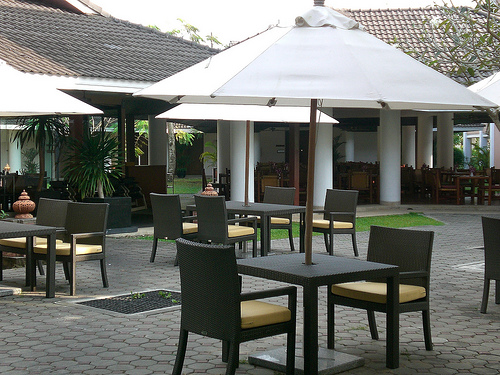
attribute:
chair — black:
[146, 190, 198, 264]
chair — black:
[192, 194, 256, 265]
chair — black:
[303, 187, 360, 258]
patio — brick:
[7, 197, 493, 371]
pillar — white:
[230, 117, 256, 212]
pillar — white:
[310, 110, 338, 212]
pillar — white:
[378, 109, 401, 207]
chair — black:
[325, 225, 433, 368]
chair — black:
[165, 237, 299, 374]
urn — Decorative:
[11, 190, 34, 227]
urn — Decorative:
[197, 185, 220, 214]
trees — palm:
[15, 112, 130, 209]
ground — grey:
[7, 204, 495, 374]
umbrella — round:
[130, 0, 487, 111]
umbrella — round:
[0, 62, 104, 114]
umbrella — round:
[152, 90, 334, 124]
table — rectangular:
[228, 252, 400, 367]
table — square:
[183, 197, 305, 249]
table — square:
[2, 220, 55, 295]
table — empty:
[226, 228, 409, 311]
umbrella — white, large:
[131, 7, 499, 375]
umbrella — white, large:
[155, 106, 340, 260]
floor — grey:
[0, 206, 498, 374]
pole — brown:
[300, 98, 323, 269]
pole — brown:
[238, 120, 255, 205]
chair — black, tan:
[41, 201, 111, 299]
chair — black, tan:
[0, 197, 72, 283]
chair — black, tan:
[144, 193, 194, 266]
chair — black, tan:
[197, 196, 257, 254]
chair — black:
[244, 188, 295, 255]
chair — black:
[480, 223, 500, 316]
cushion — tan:
[238, 295, 290, 329]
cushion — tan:
[331, 280, 425, 304]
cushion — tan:
[32, 242, 105, 257]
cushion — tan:
[0, 237, 61, 248]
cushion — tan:
[181, 221, 198, 235]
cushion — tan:
[225, 223, 255, 237]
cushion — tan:
[270, 216, 290, 225]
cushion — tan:
[311, 218, 354, 228]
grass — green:
[228, 212, 445, 243]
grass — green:
[164, 175, 209, 196]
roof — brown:
[1, 1, 227, 81]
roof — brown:
[326, 4, 499, 90]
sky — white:
[97, 0, 485, 53]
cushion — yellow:
[336, 276, 427, 299]